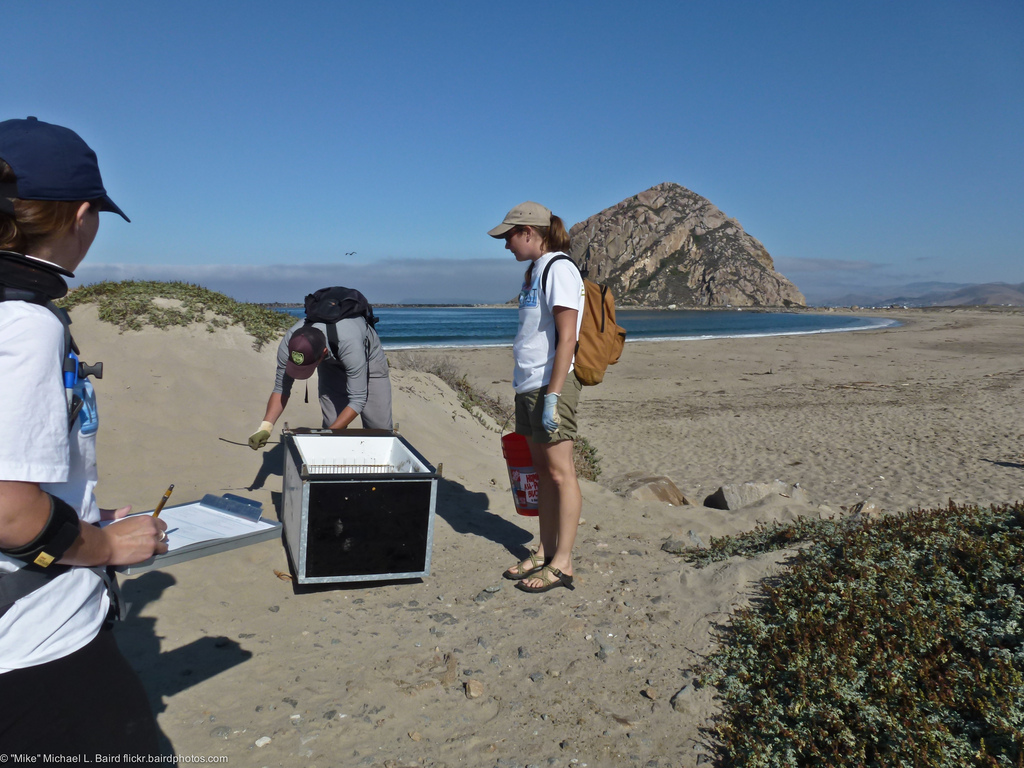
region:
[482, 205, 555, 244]
hat on woman's head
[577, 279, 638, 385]
backpack on the woman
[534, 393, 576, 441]
glove on left hand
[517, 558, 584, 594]
sandal on left foot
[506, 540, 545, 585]
right foot on woman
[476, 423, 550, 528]
orange bucket in her hand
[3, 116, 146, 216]
blue hat on woman's head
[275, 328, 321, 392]
hat on person's head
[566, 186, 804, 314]
large rock in water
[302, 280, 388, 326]
black backpack on man's back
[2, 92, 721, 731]
People on the beach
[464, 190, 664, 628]
Girl wearing brown sandals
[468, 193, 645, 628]
Girl wearing brown cap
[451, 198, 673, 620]
Girl wearing a pair of glasses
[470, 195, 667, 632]
Girl wearing a white shirt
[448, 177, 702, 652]
Girl wearing brown shorts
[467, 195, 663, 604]
Girl wearing an orange backpack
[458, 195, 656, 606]
Girl wearing blue gloves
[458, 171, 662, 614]
Girl holding an orange bucket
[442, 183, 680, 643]
Girl standing on the beach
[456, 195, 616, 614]
Woman carrying a bucket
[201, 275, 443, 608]
Man gathering samples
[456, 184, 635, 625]
Woman wearing blue gloves on hands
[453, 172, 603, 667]
Woman wearing gray sandals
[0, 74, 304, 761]
Person holding and writing on a clipboard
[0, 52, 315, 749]
Person wearing dark blue hat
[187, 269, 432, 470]
Man wearing dark hat with green logo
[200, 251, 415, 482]
Man wearing black backpack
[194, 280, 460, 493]
Man wearing green and white gloves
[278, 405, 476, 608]
a black and white container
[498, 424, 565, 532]
a red bucket with white on it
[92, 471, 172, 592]
a pencil in her hand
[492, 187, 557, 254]
a brown cap on her head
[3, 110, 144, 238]
a blue cap on her head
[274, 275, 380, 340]
a black backpack on his back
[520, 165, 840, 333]
a large rock in the water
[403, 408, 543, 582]
a shadow cast by the woman with the bucket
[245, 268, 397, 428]
man standing in tan sand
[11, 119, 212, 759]
man standing in tan sand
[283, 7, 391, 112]
white clouds in blue sky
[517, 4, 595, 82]
white clouds in blue sky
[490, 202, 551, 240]
A tan cap on a person's head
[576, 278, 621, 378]
A brown pack on a person's back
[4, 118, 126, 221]
A blue cap on a person's head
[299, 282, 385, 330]
A black pack on a person's back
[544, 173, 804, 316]
A large rock at the edge of water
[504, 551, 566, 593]
Sandals on a person's feet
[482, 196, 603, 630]
A person is standing up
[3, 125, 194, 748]
A person is standing up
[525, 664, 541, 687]
A rock in the sand.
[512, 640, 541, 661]
A rock in the sand.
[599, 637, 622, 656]
A rock in the sand.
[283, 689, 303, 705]
A rock in the sand.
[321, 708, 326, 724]
A rock in the sand.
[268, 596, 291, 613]
A rock in the sand.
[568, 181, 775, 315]
a large rock behind the people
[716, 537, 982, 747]
grass in the sand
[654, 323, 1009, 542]
sand on the beach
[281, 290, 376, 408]
a person with a black backpack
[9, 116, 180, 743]
a person in a white shirt